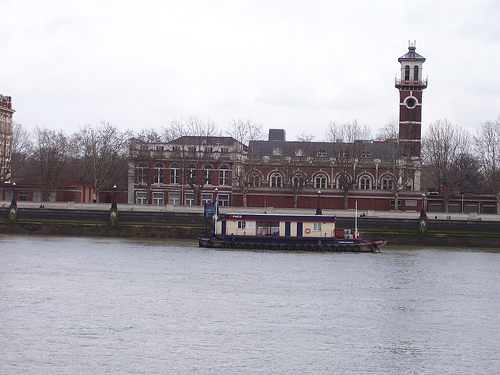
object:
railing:
[0, 199, 204, 220]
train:
[0, 206, 212, 224]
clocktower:
[394, 39, 426, 167]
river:
[0, 233, 500, 375]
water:
[0, 232, 497, 374]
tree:
[162, 116, 223, 207]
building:
[125, 35, 428, 212]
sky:
[0, 0, 500, 164]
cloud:
[214, 40, 309, 83]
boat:
[196, 202, 387, 253]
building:
[0, 179, 94, 203]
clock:
[404, 95, 419, 109]